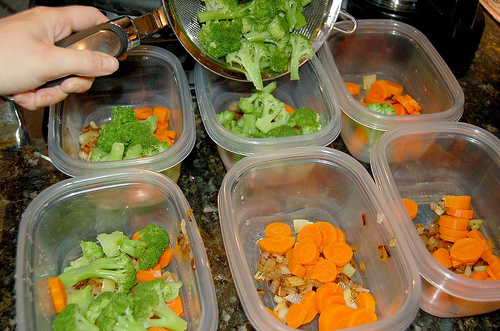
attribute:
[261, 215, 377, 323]
carrots — vegetable, cooked, sliced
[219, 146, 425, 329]
container — plastic, clear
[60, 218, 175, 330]
broccoli — vegetable, green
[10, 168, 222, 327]
container — clear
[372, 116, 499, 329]
container — plastic, clear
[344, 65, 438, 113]
carrots — orange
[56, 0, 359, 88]
strainer — metal, stainless steel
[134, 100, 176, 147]
carrots — orange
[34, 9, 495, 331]
containers — plastic, clear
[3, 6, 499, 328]
table — marble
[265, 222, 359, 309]
onions — grilled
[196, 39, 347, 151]
container — clear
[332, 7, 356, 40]
loop — metal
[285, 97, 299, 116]
carrots — sliced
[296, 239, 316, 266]
carrot — sliced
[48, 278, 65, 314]
carrot — sliced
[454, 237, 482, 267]
carrot — sliced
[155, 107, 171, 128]
carrot — sliced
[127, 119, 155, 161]
broccoli — green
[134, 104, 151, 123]
carrot — sliced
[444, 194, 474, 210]
carrot — sliced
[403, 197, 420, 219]
carrot — sliced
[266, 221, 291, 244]
carrot — sliced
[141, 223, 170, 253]
broccoli — floret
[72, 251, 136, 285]
broccoli — floret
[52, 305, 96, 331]
broccoli — finger